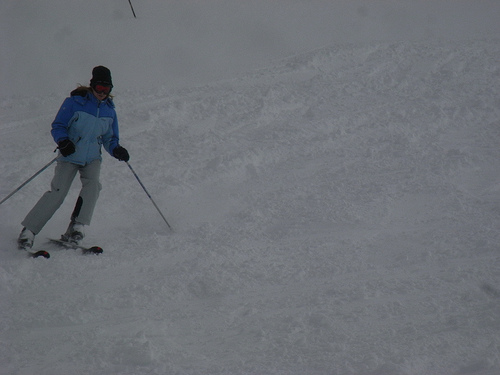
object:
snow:
[1, 0, 498, 374]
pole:
[1, 157, 62, 216]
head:
[87, 64, 114, 102]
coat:
[50, 90, 118, 162]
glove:
[112, 145, 130, 162]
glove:
[59, 139, 76, 157]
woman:
[18, 64, 130, 251]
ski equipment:
[23, 244, 51, 261]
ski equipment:
[48, 236, 104, 255]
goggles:
[90, 79, 114, 93]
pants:
[20, 156, 106, 233]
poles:
[126, 163, 176, 231]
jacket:
[53, 95, 119, 165]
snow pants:
[16, 163, 103, 235]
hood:
[70, 84, 90, 97]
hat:
[90, 65, 115, 86]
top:
[86, 244, 104, 254]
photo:
[2, 2, 483, 372]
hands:
[110, 145, 131, 163]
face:
[91, 76, 114, 100]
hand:
[56, 137, 78, 158]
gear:
[120, 160, 179, 233]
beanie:
[91, 64, 115, 86]